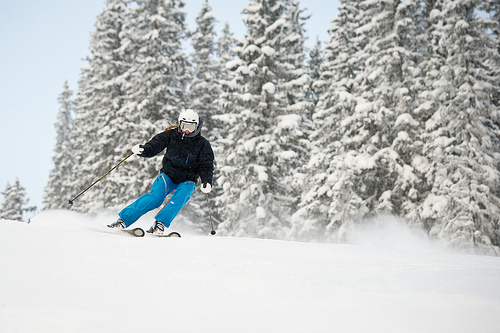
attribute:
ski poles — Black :
[65, 137, 235, 255]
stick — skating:
[67, 152, 135, 202]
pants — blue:
[117, 171, 194, 227]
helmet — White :
[174, 103, 204, 143]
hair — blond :
[163, 121, 180, 132]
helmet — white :
[154, 96, 264, 147]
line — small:
[185, 152, 194, 171]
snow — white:
[37, 230, 302, 327]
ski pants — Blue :
[120, 166, 200, 236]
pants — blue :
[126, 159, 196, 234]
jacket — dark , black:
[141, 127, 216, 184]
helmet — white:
[176, 109, 201, 129]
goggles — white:
[180, 119, 197, 131]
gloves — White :
[132, 144, 143, 155]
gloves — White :
[199, 182, 211, 192]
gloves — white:
[127, 139, 212, 196]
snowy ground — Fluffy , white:
[0, 219, 497, 331]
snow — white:
[220, 242, 466, 321]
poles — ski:
[62, 144, 133, 217]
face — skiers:
[174, 106, 202, 137]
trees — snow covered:
[42, 6, 499, 252]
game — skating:
[12, 83, 499, 326]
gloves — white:
[123, 134, 154, 163]